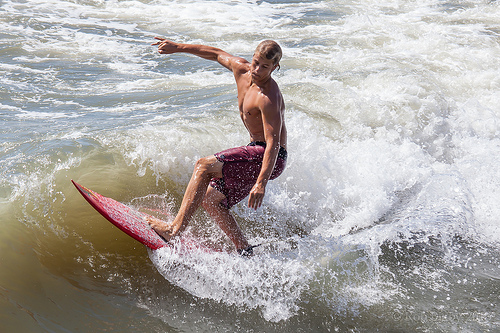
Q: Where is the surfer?
A: In the ocean.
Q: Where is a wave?
A: In the ocean.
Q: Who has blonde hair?
A: Surfer.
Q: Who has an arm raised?
A: The surfer.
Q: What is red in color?
A: Surfboard.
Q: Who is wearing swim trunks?
A: Man surfing.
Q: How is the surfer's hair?
A: Wet.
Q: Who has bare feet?
A: The surfer.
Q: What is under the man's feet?
A: A surfboard.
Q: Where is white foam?
A: In the ocean.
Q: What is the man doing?
A: Surfing.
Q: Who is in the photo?
A: A man.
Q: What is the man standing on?
A: Surfboard.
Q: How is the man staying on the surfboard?
A: Balance.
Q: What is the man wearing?
A: Shorts.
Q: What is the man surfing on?
A: Wave.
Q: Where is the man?
A: Ocean.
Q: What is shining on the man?
A: The sun.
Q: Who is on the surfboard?
A: A man.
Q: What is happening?
A: Surfing.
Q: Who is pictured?
A: Man surfing.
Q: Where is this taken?
A: The ocean.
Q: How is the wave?
A: Cresting and foamy white.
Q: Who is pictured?
A: A surfboarder.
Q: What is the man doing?
A: Surfing.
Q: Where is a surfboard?
A: Under man's feet.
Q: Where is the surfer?
A: In the ocean.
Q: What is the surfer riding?
A: A wave.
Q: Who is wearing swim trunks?
A: The surfer.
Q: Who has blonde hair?
A: Guy surfing.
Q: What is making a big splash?
A: The wave.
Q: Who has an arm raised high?
A: Surfer.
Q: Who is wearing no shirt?
A: A surfer.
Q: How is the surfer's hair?
A: Wet.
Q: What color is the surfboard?
A: Red.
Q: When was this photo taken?
A: During the day.